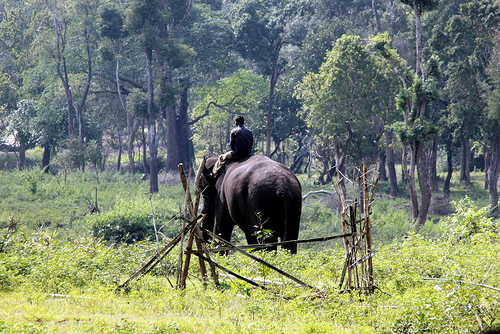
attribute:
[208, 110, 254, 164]
person — looking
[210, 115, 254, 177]
person — sitting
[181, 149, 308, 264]
elephant — carrying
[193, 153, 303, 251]
elephant — walking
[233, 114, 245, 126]
head — small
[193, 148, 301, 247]
animal — large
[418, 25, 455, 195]
tree — twisted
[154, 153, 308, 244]
elephant — walking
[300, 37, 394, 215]
tree — surrounding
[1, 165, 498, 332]
field — green, grassy